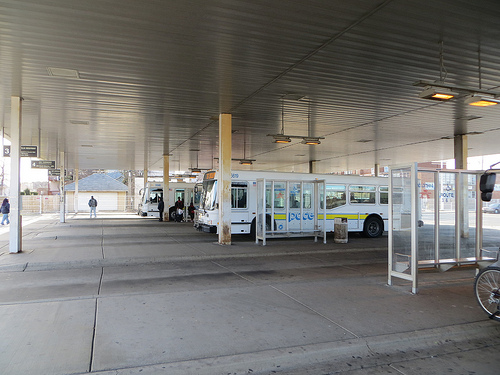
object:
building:
[67, 169, 132, 216]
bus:
[193, 169, 424, 240]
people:
[157, 197, 164, 222]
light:
[469, 100, 496, 108]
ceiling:
[6, 2, 494, 160]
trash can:
[334, 217, 349, 244]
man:
[0, 198, 9, 225]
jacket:
[0, 202, 10, 214]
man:
[88, 196, 98, 219]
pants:
[89, 206, 97, 218]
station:
[6, 47, 479, 334]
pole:
[8, 95, 22, 256]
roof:
[64, 170, 129, 192]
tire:
[473, 266, 500, 323]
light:
[432, 93, 454, 100]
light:
[300, 137, 325, 145]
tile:
[3, 11, 269, 103]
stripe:
[272, 213, 368, 221]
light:
[269, 132, 293, 143]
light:
[300, 137, 322, 146]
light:
[239, 160, 253, 165]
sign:
[30, 160, 56, 170]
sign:
[2, 145, 38, 157]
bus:
[138, 181, 209, 221]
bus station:
[2, 0, 499, 373]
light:
[272, 133, 292, 143]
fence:
[17, 188, 147, 218]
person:
[175, 197, 185, 223]